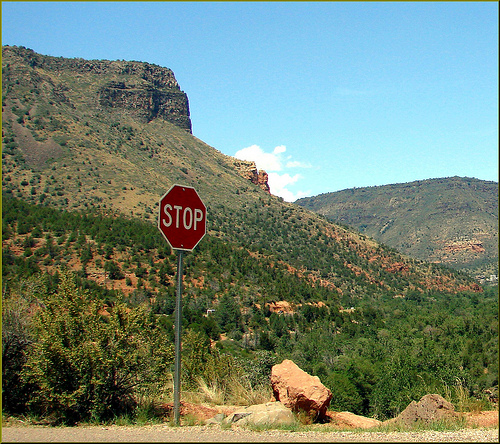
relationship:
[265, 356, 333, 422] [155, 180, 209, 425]
rock near stop sign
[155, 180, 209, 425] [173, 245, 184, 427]
stop sign connected to pole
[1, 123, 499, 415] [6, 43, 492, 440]
trees on mountainside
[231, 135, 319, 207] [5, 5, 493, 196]
clouds in sky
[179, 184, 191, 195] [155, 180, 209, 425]
bolt holding stop sign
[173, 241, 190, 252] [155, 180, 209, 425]
bolt holding stop sign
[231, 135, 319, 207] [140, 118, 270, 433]
clouds behind mountain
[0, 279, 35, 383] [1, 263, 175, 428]
bush surrounded by bush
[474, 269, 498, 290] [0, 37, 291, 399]
buildings behind mountain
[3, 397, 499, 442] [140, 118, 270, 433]
road shoulder in mountain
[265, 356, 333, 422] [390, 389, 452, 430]
rock by rock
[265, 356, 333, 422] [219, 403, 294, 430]
rock by rock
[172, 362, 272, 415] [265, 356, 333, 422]
brush by rock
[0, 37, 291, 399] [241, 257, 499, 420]
mountain overlooking prairie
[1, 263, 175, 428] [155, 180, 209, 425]
bush near stop sign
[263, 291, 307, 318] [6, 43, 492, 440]
patch on mountainside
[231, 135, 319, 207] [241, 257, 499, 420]
clouds overlooking prairie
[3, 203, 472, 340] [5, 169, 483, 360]
bushes dotting foot of hill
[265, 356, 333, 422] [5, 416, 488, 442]
rock laying on path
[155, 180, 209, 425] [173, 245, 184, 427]
stop sign on pole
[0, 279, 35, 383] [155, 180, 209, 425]
bush near stop sign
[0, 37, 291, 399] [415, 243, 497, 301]
mountain overlooking valley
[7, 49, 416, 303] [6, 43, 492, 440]
vegetation on mountainside